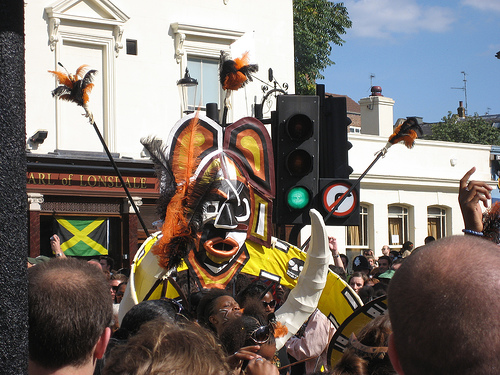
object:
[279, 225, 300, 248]
pole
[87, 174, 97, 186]
letter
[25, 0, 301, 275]
wall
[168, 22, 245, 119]
frame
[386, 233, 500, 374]
head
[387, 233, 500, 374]
hair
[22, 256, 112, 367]
hair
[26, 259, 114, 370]
head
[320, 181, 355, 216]
sign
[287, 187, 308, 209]
green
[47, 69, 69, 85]
feathers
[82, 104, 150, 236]
stick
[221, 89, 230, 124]
stick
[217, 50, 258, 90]
feathers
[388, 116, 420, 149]
feathers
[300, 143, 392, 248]
stick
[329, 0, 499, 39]
clouds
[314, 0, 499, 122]
sky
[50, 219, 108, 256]
flag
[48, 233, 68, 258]
person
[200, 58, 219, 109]
window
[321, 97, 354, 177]
street light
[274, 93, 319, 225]
street light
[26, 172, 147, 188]
business name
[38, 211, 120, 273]
door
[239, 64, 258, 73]
feathers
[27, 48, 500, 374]
crowd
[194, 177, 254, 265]
face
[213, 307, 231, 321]
face paint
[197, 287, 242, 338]
woman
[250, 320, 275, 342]
sunglasses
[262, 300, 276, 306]
sunglasses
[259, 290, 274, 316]
face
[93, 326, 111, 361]
ear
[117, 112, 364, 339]
person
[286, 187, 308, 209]
light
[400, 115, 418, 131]
feathers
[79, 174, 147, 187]
writing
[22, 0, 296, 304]
building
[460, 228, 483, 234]
bracelet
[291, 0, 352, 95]
tree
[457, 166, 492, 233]
hand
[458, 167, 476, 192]
finger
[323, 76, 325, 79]
leaves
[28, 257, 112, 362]
back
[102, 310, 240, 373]
hair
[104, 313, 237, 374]
someone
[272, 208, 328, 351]
horn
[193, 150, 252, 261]
mask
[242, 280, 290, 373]
person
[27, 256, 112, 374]
person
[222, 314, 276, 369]
head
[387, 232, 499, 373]
person